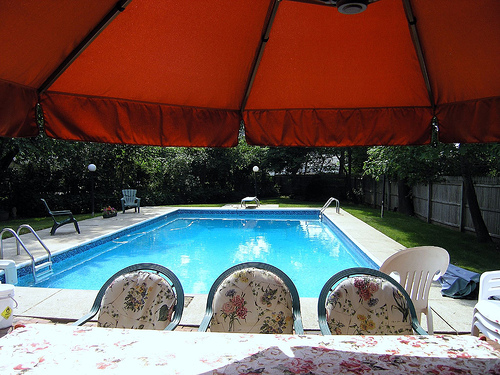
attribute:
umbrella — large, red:
[0, 2, 499, 152]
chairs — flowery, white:
[75, 257, 434, 334]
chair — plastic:
[35, 185, 152, 236]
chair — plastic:
[364, 221, 500, 342]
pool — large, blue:
[29, 200, 414, 304]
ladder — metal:
[1, 217, 67, 285]